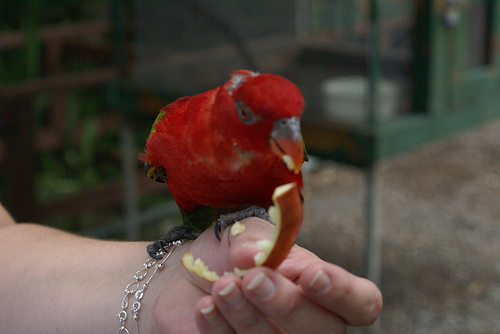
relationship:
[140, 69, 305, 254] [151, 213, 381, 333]
bird fed by hand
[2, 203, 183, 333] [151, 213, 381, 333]
person has hand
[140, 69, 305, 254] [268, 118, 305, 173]
bird has beak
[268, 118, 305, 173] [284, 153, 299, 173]
beak has food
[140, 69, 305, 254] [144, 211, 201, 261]
bird has claw foot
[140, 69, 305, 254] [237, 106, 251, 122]
bird has right eye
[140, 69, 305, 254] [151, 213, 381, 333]
bird standing on hand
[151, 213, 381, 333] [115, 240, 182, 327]
hand has bracelet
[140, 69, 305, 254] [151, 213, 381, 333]
bird eating out of hand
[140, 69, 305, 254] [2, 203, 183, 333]
bird fed by person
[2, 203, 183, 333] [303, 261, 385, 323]
person has finger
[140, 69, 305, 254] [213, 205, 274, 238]
bird has talons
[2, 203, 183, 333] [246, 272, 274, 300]
person has fingernail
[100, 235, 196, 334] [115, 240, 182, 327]
wrist has bracelet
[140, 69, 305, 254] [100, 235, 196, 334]
bird standing on wrist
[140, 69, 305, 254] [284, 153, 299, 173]
bird eating food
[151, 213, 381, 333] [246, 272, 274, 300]
hand has fingernail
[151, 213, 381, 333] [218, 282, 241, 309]
hand has fingernail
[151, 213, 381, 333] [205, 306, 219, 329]
hand has fingernail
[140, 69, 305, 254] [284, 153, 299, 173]
bird has food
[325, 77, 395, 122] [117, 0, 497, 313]
bowl inside bird cage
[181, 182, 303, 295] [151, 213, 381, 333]
red apple inside a hand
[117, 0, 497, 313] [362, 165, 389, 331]
bird cage has support leg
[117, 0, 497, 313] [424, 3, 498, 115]
bird cage has door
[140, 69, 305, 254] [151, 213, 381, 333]
bird sitting on hand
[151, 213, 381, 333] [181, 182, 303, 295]
hand holding red apple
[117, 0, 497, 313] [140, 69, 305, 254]
bird cage behind bird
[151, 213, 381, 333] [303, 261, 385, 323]
hand has finger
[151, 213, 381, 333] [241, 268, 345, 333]
hand has finger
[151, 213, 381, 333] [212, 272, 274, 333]
hand has finger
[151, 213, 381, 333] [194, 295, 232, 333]
hand has finger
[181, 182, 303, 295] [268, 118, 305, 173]
red apple inside beak